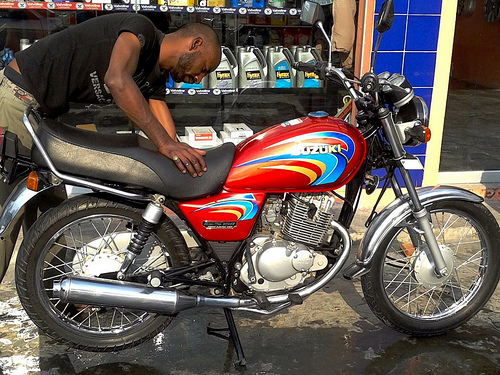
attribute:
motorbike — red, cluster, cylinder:
[0, 3, 500, 369]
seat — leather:
[37, 117, 238, 203]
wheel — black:
[16, 192, 193, 351]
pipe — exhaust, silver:
[50, 277, 206, 319]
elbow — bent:
[101, 66, 134, 91]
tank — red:
[224, 110, 367, 194]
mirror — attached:
[300, 1, 318, 27]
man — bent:
[2, 12, 223, 214]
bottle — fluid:
[237, 45, 270, 92]